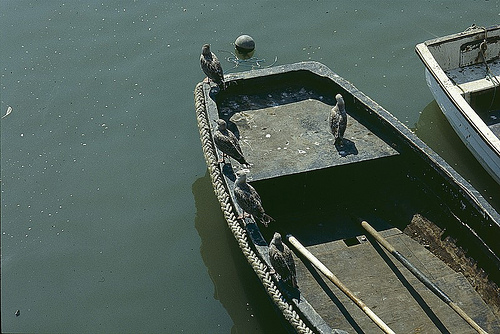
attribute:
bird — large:
[326, 90, 349, 146]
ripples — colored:
[42, 57, 142, 134]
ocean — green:
[4, 5, 496, 326]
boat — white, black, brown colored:
[196, 61, 498, 330]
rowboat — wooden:
[189, 61, 499, 332]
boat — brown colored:
[178, 26, 483, 331]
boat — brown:
[171, 36, 461, 332]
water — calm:
[21, 85, 211, 273]